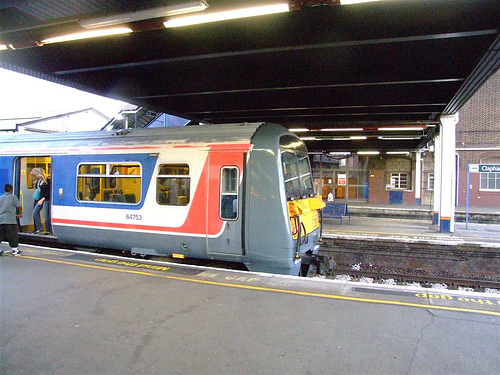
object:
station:
[0, 1, 500, 375]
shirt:
[0, 192, 22, 224]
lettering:
[94, 258, 170, 271]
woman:
[30, 167, 51, 234]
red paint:
[203, 207, 215, 224]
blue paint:
[0, 151, 160, 211]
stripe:
[1, 242, 500, 317]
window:
[74, 161, 142, 205]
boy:
[0, 183, 23, 256]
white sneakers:
[11, 247, 21, 256]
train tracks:
[318, 234, 499, 285]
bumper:
[287, 194, 327, 240]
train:
[0, 121, 327, 276]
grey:
[248, 219, 275, 235]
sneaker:
[12, 247, 22, 256]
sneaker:
[0, 249, 4, 256]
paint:
[0, 121, 327, 277]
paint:
[287, 195, 327, 240]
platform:
[2, 240, 499, 372]